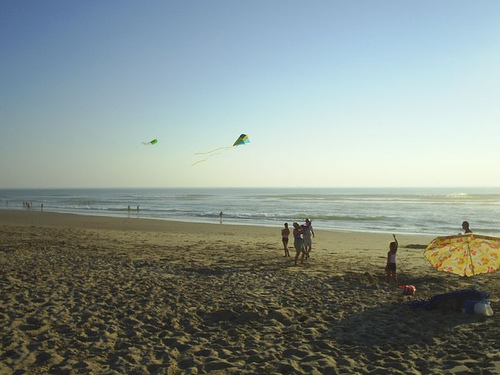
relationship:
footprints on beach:
[116, 274, 227, 373] [82, 222, 275, 342]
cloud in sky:
[119, 117, 210, 183] [0, 0, 497, 126]